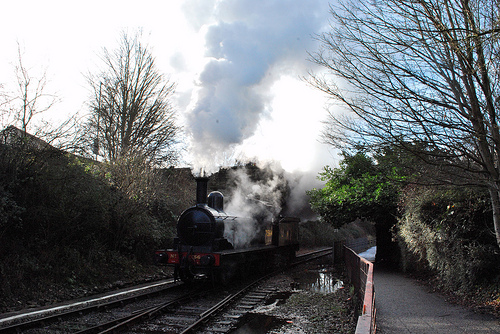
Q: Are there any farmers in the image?
A: No, there are no farmers.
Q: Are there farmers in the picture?
A: No, there are no farmers.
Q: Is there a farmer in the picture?
A: No, there are no farmers.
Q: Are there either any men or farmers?
A: No, there are no farmers or men.